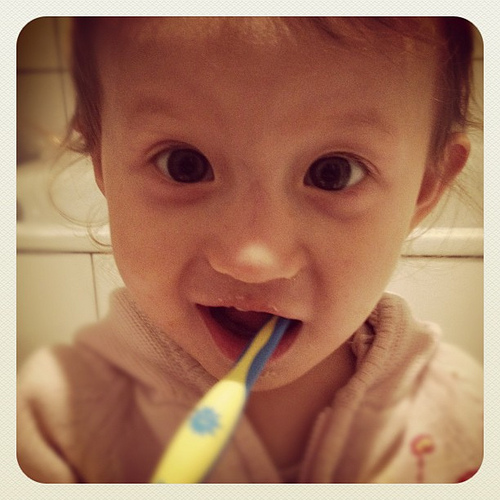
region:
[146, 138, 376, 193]
The child is looking at the camera.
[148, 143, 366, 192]
The child has brown eyes.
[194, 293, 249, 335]
The child's mouth is open.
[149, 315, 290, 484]
A toothbrush is in the child's mouth.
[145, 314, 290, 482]
The toothbrush is yellow and blue.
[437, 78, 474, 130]
The child has wispy hair.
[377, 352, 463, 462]
The child's sweater is white.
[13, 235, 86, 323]
A bathroom counter is behind the child.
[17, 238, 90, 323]
The counter is white.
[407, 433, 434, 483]
A red pattern is on the child's sweater.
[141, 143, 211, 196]
eye of the kid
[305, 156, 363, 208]
eye of the kid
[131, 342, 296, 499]
toothbrush in kids mouth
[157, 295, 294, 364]
mouth of the kid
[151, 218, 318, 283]
nose of the kid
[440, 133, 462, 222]
ear of the kid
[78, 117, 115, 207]
ear of the kid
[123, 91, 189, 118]
eye brow of the kid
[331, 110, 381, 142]
eye brow of the kid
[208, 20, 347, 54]
bangs of the kid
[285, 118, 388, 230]
Small human eye on face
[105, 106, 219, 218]
Small human eye on face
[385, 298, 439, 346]
Small peice of cloth on child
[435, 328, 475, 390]
Small peice of cloth on child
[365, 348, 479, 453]
Small peice of cloth on child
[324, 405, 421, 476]
Small peice of cloth on child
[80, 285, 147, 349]
Small peice of cloth on child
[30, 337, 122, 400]
Small peice of cloth on child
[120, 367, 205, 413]
Small peice of cloth on child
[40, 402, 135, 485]
Small peice of cloth on child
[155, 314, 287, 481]
blue and yellow toothbrush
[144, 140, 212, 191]
big dark right eye of kid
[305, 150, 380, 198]
big dark left eye of kid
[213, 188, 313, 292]
big nose of little kid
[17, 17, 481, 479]
little kid brushing his tooth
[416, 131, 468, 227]
little left ear of kid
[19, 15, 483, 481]
blonde kid with big eyes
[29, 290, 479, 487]
pinkcake bathrobe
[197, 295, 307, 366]
pinky lips of little kid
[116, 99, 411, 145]
two blonde eyebrows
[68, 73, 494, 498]
a child brushing thier teeth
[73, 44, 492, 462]
a child with large eyes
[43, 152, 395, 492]
a child with a toothbrush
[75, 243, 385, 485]
child with toothbrush in mouth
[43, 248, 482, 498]
kid brushing their teet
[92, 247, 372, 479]
kid with tooth brush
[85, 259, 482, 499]
yellow and blue toothbrush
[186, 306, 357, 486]
a toothbrush that is kids size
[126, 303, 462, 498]
yellow and blue kid size toothbrush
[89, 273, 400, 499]
toothbursh that is yellow and blue